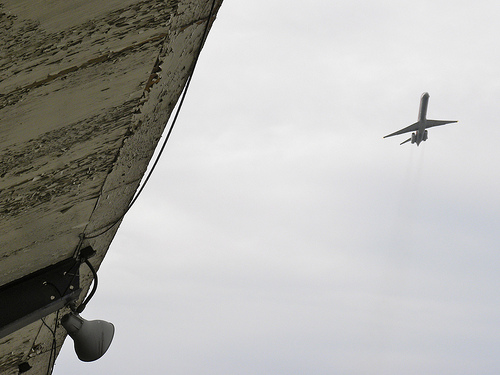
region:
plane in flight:
[381, 80, 449, 165]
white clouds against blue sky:
[226, 19, 270, 93]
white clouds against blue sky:
[189, 90, 270, 162]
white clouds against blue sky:
[158, 211, 232, 276]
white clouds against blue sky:
[158, 267, 212, 328]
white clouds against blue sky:
[245, 244, 317, 345]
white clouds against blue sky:
[245, 154, 329, 225]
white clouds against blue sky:
[346, 189, 444, 260]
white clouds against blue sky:
[305, 270, 422, 370]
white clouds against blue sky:
[421, 249, 481, 353]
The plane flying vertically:
[384, 93, 461, 148]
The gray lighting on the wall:
[57, 303, 117, 373]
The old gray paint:
[0, 0, 229, 374]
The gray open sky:
[51, 2, 498, 373]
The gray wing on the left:
[386, 119, 421, 143]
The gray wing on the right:
[425, 115, 458, 130]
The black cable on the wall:
[58, 2, 218, 363]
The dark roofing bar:
[0, 247, 100, 341]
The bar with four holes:
[42, 269, 77, 301]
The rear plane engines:
[411, 131, 428, 146]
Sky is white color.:
[186, 185, 385, 297]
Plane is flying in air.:
[385, 74, 472, 157]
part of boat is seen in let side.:
[20, 42, 192, 221]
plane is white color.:
[386, 77, 474, 179]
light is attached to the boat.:
[18, 255, 148, 365]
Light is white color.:
[38, 297, 124, 359]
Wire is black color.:
[69, 262, 107, 313]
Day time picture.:
[11, 17, 478, 329]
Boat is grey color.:
[23, 118, 143, 250]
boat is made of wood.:
[32, 52, 190, 220]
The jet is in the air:
[385, 90, 453, 151]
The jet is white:
[385, 80, 455, 150]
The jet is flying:
[385, 86, 455, 156]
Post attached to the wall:
[5, 0, 200, 360]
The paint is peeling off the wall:
[5, 1, 200, 366]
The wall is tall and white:
[65, 310, 125, 361]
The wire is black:
[70, 25, 210, 280]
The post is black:
[0, 245, 101, 345]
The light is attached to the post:
[1, 245, 118, 365]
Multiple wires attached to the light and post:
[36, 258, 103, 365]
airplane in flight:
[382, 84, 473, 155]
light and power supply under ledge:
[43, 220, 150, 363]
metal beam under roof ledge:
[1, 265, 87, 335]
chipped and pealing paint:
[26, 121, 123, 208]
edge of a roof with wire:
[148, 4, 224, 191]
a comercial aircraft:
[371, 78, 478, 157]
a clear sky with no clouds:
[242, 103, 343, 195]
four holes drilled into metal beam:
[36, 261, 86, 308]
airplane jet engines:
[401, 127, 440, 149]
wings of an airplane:
[373, 115, 477, 138]